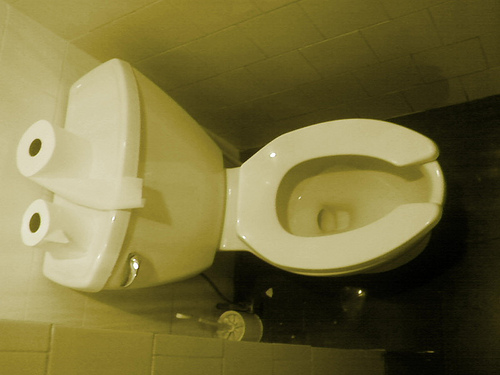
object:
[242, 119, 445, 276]
bowl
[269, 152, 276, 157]
glare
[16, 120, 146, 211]
paper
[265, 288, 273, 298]
paper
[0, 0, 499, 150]
wall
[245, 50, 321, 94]
tile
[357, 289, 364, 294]
glare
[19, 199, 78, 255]
roll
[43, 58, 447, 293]
toilet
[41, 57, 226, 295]
tank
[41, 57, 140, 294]
lid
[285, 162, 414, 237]
water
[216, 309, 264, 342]
container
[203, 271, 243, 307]
water line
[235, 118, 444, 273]
seat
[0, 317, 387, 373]
wall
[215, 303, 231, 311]
pipe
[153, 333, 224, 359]
brick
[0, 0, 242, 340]
wall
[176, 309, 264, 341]
brush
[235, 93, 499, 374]
floor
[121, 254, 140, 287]
handle